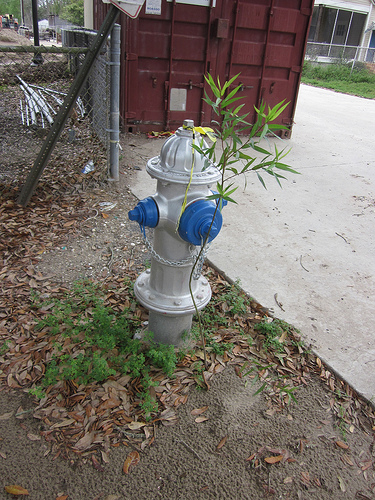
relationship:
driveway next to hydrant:
[125, 63, 372, 381] [116, 118, 230, 333]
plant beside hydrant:
[182, 78, 275, 309] [116, 118, 230, 333]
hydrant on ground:
[116, 118, 230, 333] [2, 199, 360, 493]